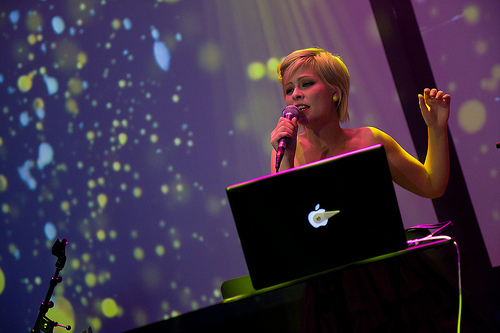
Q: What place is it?
A: It is a stage.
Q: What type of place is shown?
A: It is a stage.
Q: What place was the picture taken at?
A: It was taken at the stage.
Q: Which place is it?
A: It is a stage.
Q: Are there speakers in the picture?
A: No, there are no speakers.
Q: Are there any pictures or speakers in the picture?
A: No, there are no speakers or pictures.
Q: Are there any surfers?
A: No, there are no surfers.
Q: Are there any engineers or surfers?
A: No, there are no surfers or engineers.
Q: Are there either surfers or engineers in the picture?
A: No, there are no surfers or engineers.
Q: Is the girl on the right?
A: Yes, the girl is on the right of the image.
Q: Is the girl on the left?
A: No, the girl is on the right of the image.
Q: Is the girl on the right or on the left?
A: The girl is on the right of the image.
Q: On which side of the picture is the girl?
A: The girl is on the right of the image.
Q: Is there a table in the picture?
A: Yes, there is a table.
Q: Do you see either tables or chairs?
A: Yes, there is a table.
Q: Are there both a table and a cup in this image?
A: No, there is a table but no cups.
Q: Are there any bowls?
A: No, there are no bowls.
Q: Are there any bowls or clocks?
A: No, there are no bowls or clocks.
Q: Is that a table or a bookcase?
A: That is a table.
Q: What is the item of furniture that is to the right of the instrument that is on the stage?
A: The piece of furniture is a table.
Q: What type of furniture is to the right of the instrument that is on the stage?
A: The piece of furniture is a table.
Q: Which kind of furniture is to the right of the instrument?
A: The piece of furniture is a table.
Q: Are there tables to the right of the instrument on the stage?
A: Yes, there is a table to the right of the instrument.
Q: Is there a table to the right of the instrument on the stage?
A: Yes, there is a table to the right of the instrument.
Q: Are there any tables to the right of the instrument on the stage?
A: Yes, there is a table to the right of the instrument.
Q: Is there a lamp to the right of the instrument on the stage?
A: No, there is a table to the right of the instrument.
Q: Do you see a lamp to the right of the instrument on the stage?
A: No, there is a table to the right of the instrument.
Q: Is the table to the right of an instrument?
A: Yes, the table is to the right of an instrument.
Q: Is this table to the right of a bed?
A: No, the table is to the right of an instrument.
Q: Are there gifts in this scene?
A: No, there are no gifts.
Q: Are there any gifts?
A: No, there are no gifts.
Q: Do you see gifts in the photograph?
A: No, there are no gifts.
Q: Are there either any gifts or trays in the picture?
A: No, there are no gifts or trays.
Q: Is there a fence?
A: No, there are no fences.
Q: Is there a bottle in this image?
A: No, there are no bottles.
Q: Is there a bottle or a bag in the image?
A: No, there are no bottles or bags.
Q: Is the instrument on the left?
A: Yes, the instrument is on the left of the image.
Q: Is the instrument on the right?
A: No, the instrument is on the left of the image.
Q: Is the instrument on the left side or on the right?
A: The instrument is on the left of the image.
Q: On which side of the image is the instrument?
A: The instrument is on the left of the image.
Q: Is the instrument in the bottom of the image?
A: Yes, the instrument is in the bottom of the image.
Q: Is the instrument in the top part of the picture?
A: No, the instrument is in the bottom of the image.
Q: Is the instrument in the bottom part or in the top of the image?
A: The instrument is in the bottom of the image.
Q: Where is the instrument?
A: The instrument is on the stage.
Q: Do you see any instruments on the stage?
A: Yes, there is an instrument on the stage.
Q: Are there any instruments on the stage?
A: Yes, there is an instrument on the stage.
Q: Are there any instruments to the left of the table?
A: Yes, there is an instrument to the left of the table.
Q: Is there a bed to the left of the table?
A: No, there is an instrument to the left of the table.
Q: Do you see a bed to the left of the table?
A: No, there is an instrument to the left of the table.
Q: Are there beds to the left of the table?
A: No, there is an instrument to the left of the table.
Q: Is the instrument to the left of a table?
A: Yes, the instrument is to the left of a table.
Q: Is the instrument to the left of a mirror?
A: No, the instrument is to the left of a table.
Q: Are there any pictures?
A: No, there are no pictures.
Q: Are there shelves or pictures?
A: No, there are no pictures or shelves.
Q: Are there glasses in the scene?
A: No, there are no glasses.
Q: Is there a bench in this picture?
A: No, there are no benches.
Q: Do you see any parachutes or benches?
A: No, there are no benches or parachutes.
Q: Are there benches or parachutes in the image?
A: No, there are no benches or parachutes.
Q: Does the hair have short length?
A: Yes, the hair is short.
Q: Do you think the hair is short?
A: Yes, the hair is short.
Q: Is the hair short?
A: Yes, the hair is short.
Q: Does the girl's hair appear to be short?
A: Yes, the hair is short.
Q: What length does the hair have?
A: The hair has short length.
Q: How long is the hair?
A: The hair is short.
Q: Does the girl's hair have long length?
A: No, the hair is short.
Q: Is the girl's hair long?
A: No, the hair is short.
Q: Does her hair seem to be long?
A: No, the hair is short.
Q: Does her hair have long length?
A: No, the hair is short.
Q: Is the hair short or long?
A: The hair is short.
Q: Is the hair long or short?
A: The hair is short.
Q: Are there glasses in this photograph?
A: No, there are no glasses.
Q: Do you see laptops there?
A: Yes, there is a laptop.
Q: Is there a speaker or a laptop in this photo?
A: Yes, there is a laptop.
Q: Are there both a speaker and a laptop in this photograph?
A: No, there is a laptop but no speakers.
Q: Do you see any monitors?
A: No, there are no monitors.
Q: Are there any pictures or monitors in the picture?
A: No, there are no monitors or pictures.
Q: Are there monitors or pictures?
A: No, there are no monitors or pictures.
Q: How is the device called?
A: The device is a laptop.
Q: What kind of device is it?
A: The device is a laptop.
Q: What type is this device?
A: That is a laptop.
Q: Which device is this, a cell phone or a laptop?
A: That is a laptop.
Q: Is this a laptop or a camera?
A: This is a laptop.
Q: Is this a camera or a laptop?
A: This is a laptop.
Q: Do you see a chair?
A: Yes, there is a chair.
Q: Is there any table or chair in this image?
A: Yes, there is a chair.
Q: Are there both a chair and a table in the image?
A: Yes, there are both a chair and a table.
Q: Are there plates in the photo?
A: No, there are no plates.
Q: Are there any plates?
A: No, there are no plates.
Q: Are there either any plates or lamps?
A: No, there are no plates or lamps.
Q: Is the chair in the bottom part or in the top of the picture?
A: The chair is in the bottom of the image.